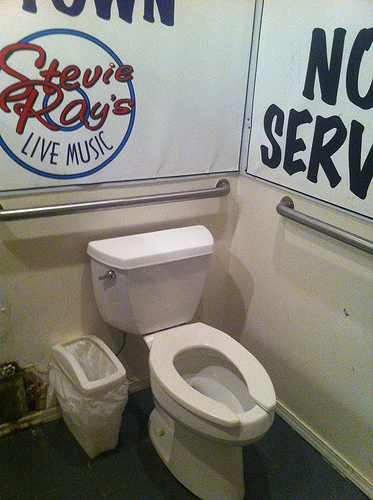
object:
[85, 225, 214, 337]
tank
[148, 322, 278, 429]
toilet seat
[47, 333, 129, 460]
trash can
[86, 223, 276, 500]
toilet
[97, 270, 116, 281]
lever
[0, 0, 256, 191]
sign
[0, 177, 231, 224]
metal bar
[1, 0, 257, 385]
wall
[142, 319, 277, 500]
bowl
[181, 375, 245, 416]
water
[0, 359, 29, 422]
wall stain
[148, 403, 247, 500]
base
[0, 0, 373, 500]
bathroom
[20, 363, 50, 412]
hole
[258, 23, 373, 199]
letters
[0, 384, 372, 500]
floor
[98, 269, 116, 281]
handle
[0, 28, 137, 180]
logo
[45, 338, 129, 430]
bag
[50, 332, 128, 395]
lid